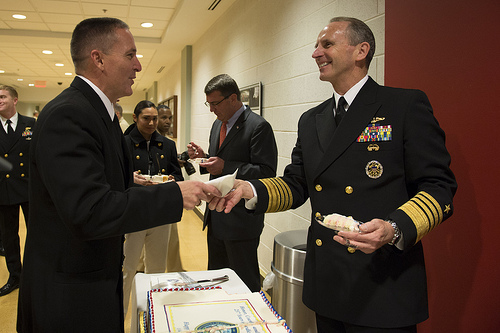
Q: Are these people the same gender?
A: No, they are both male and female.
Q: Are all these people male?
A: No, they are both male and female.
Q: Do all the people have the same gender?
A: No, they are both male and female.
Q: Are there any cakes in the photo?
A: Yes, there is a cake.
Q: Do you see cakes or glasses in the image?
A: Yes, there is a cake.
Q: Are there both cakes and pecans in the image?
A: No, there is a cake but no pecans.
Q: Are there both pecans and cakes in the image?
A: No, there is a cake but no pecans.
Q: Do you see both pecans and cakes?
A: No, there is a cake but no pecans.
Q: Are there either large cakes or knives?
A: Yes, there is a large cake.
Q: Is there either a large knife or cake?
A: Yes, there is a large cake.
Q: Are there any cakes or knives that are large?
A: Yes, the cake is large.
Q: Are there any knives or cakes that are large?
A: Yes, the cake is large.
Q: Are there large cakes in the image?
A: Yes, there is a large cake.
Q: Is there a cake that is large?
A: Yes, there is a cake that is large.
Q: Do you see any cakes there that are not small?
A: Yes, there is a large cake.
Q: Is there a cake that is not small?
A: Yes, there is a large cake.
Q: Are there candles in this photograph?
A: No, there are no candles.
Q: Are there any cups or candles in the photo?
A: No, there are no candles or cups.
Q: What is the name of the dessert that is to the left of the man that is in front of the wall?
A: The dessert is a cake.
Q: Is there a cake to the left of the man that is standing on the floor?
A: Yes, there is a cake to the left of the man.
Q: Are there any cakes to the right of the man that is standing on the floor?
A: No, the cake is to the left of the man.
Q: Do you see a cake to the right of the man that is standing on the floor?
A: No, the cake is to the left of the man.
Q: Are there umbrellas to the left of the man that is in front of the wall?
A: No, there is a cake to the left of the man.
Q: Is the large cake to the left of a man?
A: Yes, the cake is to the left of a man.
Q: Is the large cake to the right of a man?
A: No, the cake is to the left of a man.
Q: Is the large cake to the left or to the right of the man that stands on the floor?
A: The cake is to the left of the man.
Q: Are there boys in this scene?
A: No, there are no boys.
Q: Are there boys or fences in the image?
A: No, there are no boys or fences.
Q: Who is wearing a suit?
A: The man is wearing a suit.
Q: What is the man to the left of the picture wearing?
A: The man is wearing a suit.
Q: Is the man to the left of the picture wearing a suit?
A: Yes, the man is wearing a suit.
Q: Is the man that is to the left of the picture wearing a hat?
A: No, the man is wearing a suit.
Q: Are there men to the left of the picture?
A: Yes, there is a man to the left of the picture.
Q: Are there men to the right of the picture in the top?
A: No, the man is to the left of the picture.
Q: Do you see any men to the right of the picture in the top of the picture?
A: No, the man is to the left of the picture.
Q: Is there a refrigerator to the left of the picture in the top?
A: No, there is a man to the left of the picture.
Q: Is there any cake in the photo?
A: Yes, there is a cake.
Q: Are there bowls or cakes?
A: Yes, there is a cake.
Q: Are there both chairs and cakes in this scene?
A: No, there is a cake but no chairs.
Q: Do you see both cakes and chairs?
A: No, there is a cake but no chairs.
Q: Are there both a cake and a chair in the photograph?
A: No, there is a cake but no chairs.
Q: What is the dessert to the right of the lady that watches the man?
A: The dessert is a cake.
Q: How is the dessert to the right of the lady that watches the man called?
A: The dessert is a cake.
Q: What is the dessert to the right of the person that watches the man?
A: The dessert is a cake.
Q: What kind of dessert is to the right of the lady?
A: The dessert is a cake.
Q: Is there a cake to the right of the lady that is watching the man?
A: Yes, there is a cake to the right of the lady.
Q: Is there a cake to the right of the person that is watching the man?
A: Yes, there is a cake to the right of the lady.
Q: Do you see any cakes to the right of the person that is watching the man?
A: Yes, there is a cake to the right of the lady.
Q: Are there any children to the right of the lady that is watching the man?
A: No, there is a cake to the right of the lady.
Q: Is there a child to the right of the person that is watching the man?
A: No, there is a cake to the right of the lady.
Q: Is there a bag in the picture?
A: No, there are no bags.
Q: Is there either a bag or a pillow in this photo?
A: No, there are no bags or pillows.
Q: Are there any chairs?
A: No, there are no chairs.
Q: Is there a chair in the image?
A: No, there are no chairs.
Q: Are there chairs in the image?
A: No, there are no chairs.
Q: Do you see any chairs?
A: No, there are no chairs.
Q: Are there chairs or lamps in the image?
A: No, there are no chairs or lamps.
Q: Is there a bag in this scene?
A: No, there are no bags.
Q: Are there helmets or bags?
A: No, there are no bags or helmets.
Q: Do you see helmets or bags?
A: No, there are no bags or helmets.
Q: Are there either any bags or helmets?
A: No, there are no bags or helmets.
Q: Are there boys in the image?
A: No, there are no boys.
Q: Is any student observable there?
A: No, there are no students.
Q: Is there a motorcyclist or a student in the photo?
A: No, there are no students or bikers.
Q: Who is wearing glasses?
A: The man is wearing glasses.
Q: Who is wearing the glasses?
A: The man is wearing glasses.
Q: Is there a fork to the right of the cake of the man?
A: No, there is a man to the right of the cake.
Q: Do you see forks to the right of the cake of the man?
A: No, there is a man to the right of the cake.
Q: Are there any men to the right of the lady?
A: Yes, there is a man to the right of the lady.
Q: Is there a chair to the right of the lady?
A: No, there is a man to the right of the lady.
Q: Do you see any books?
A: No, there are no books.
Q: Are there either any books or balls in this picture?
A: No, there are no books or balls.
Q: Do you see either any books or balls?
A: No, there are no books or balls.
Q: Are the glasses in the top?
A: Yes, the glasses are in the top of the image.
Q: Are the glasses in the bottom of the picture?
A: No, the glasses are in the top of the image.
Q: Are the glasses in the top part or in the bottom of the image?
A: The glasses are in the top of the image.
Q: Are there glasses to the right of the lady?
A: Yes, there are glasses to the right of the lady.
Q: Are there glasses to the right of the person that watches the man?
A: Yes, there are glasses to the right of the lady.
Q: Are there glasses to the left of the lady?
A: No, the glasses are to the right of the lady.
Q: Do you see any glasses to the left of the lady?
A: No, the glasses are to the right of the lady.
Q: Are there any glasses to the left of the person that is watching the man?
A: No, the glasses are to the right of the lady.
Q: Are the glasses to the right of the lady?
A: Yes, the glasses are to the right of the lady.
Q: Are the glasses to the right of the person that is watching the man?
A: Yes, the glasses are to the right of the lady.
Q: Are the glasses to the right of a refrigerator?
A: No, the glasses are to the right of the lady.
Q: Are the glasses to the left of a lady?
A: No, the glasses are to the right of a lady.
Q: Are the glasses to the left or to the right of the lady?
A: The glasses are to the right of the lady.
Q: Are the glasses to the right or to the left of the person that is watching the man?
A: The glasses are to the right of the lady.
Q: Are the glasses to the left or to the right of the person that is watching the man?
A: The glasses are to the right of the lady.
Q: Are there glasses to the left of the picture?
A: Yes, there are glasses to the left of the picture.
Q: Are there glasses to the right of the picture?
A: No, the glasses are to the left of the picture.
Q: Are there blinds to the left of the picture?
A: No, there are glasses to the left of the picture.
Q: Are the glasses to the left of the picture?
A: Yes, the glasses are to the left of the picture.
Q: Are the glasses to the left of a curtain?
A: No, the glasses are to the left of the picture.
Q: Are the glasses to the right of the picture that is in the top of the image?
A: No, the glasses are to the left of the picture.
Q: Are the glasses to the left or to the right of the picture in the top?
A: The glasses are to the left of the picture.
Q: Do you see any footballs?
A: No, there are no footballs.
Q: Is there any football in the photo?
A: No, there are no footballs.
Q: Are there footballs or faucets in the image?
A: No, there are no footballs or faucets.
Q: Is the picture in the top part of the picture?
A: Yes, the picture is in the top of the image.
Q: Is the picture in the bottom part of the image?
A: No, the picture is in the top of the image.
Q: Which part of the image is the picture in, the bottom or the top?
A: The picture is in the top of the image.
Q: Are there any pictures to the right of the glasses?
A: Yes, there is a picture to the right of the glasses.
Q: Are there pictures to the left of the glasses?
A: No, the picture is to the right of the glasses.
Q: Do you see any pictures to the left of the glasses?
A: No, the picture is to the right of the glasses.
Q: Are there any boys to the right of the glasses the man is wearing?
A: No, there is a picture to the right of the glasses.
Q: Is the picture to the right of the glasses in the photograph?
A: Yes, the picture is to the right of the glasses.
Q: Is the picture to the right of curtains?
A: No, the picture is to the right of the glasses.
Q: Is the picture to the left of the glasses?
A: No, the picture is to the right of the glasses.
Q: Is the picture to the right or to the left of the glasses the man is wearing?
A: The picture is to the right of the glasses.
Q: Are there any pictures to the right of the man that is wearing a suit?
A: Yes, there is a picture to the right of the man.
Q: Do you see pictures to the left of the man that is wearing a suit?
A: No, the picture is to the right of the man.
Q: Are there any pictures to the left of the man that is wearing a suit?
A: No, the picture is to the right of the man.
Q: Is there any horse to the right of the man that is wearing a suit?
A: No, there is a picture to the right of the man.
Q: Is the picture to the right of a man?
A: Yes, the picture is to the right of a man.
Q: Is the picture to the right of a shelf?
A: No, the picture is to the right of a man.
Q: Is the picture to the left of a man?
A: No, the picture is to the right of a man.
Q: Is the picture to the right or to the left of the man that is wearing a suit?
A: The picture is to the right of the man.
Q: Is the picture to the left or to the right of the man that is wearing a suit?
A: The picture is to the right of the man.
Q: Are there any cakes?
A: Yes, there is a cake.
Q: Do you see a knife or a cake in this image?
A: Yes, there is a cake.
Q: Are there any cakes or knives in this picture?
A: Yes, there is a cake.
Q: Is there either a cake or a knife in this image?
A: Yes, there is a cake.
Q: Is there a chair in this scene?
A: No, there are no chairs.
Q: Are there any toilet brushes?
A: No, there are no toilet brushes.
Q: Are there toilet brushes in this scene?
A: No, there are no toilet brushes.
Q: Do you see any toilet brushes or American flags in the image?
A: No, there are no toilet brushes or American flags.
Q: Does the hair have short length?
A: Yes, the hair is short.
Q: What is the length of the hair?
A: The hair is short.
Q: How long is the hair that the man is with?
A: The hair is short.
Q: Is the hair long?
A: No, the hair is short.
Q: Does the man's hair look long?
A: No, the hair is short.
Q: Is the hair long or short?
A: The hair is short.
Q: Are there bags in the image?
A: No, there are no bags.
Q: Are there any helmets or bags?
A: No, there are no bags or helmets.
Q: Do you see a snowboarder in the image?
A: No, there are no snowboarders.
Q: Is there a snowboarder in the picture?
A: No, there are no snowboarders.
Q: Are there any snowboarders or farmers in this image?
A: No, there are no snowboarders or farmers.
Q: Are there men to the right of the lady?
A: Yes, there is a man to the right of the lady.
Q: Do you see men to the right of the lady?
A: Yes, there is a man to the right of the lady.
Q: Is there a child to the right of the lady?
A: No, there is a man to the right of the lady.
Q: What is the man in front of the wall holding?
A: The man is holding the cake.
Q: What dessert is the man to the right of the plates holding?
A: The man is holding the cake.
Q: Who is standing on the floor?
A: The man is standing on the floor.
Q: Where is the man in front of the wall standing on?
A: The man is standing on the floor.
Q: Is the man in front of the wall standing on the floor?
A: Yes, the man is standing on the floor.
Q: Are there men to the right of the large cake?
A: Yes, there is a man to the right of the cake.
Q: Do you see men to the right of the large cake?
A: Yes, there is a man to the right of the cake.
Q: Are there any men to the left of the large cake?
A: No, the man is to the right of the cake.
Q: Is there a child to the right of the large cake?
A: No, there is a man to the right of the cake.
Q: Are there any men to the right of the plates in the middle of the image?
A: Yes, there is a man to the right of the plates.